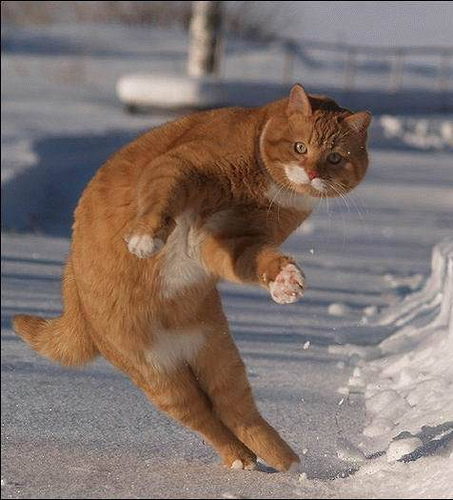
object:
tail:
[8, 245, 94, 374]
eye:
[292, 140, 307, 156]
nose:
[305, 164, 322, 181]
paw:
[127, 224, 158, 262]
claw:
[272, 269, 305, 306]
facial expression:
[265, 107, 368, 199]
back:
[67, 96, 258, 254]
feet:
[254, 422, 300, 474]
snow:
[410, 344, 448, 378]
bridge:
[291, 34, 447, 78]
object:
[114, 72, 235, 112]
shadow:
[0, 134, 76, 234]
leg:
[205, 340, 304, 478]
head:
[258, 82, 372, 200]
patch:
[169, 218, 204, 280]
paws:
[265, 262, 305, 311]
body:
[78, 91, 268, 363]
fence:
[269, 36, 409, 79]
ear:
[285, 85, 314, 120]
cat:
[14, 78, 375, 476]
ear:
[341, 109, 374, 134]